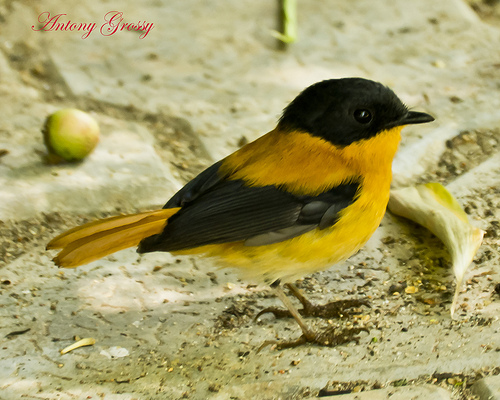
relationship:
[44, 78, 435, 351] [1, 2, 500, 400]
bird on ground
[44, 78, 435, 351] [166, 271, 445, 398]
bird standing on rock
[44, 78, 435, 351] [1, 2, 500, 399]
bird standing outside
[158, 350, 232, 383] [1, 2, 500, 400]
seed on ground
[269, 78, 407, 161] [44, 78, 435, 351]
head of bird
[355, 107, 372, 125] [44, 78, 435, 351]
eye of bird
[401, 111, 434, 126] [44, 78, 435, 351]
beak of bird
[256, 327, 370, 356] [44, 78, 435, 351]
foot of bird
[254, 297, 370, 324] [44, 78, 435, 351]
foot of bird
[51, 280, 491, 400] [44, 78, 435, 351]
area under bird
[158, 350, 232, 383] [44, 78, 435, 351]
seed near bird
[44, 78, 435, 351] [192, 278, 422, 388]
bird standing in dirt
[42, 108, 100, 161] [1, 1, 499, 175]
fruit in background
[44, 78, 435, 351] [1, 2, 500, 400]
bird standing on ground